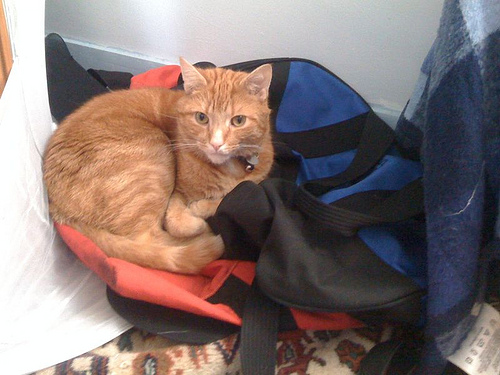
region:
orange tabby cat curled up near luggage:
[43, 57, 280, 266]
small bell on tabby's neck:
[235, 149, 267, 176]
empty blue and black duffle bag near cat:
[157, 47, 454, 330]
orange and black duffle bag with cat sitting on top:
[40, 58, 369, 342]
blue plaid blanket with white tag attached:
[385, 0, 497, 369]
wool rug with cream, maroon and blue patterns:
[34, 319, 437, 374]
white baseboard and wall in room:
[55, 0, 445, 132]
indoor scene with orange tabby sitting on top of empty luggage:
[34, 0, 499, 372]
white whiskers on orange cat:
[159, 138, 279, 161]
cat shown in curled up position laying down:
[41, 56, 288, 270]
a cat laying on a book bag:
[22, 14, 476, 374]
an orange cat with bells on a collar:
[38, 46, 313, 297]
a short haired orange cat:
[37, 47, 342, 311]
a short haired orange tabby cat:
[28, 54, 338, 326]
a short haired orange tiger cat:
[44, 49, 331, 284]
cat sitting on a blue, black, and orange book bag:
[56, 25, 443, 335]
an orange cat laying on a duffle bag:
[31, 48, 456, 335]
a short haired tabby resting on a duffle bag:
[38, 50, 425, 352]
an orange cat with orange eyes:
[28, 19, 405, 318]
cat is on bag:
[63, 50, 308, 269]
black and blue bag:
[194, 69, 446, 331]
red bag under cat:
[55, 217, 330, 346]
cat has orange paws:
[149, 192, 236, 265]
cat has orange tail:
[94, 213, 225, 322]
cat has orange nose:
[182, 135, 234, 147]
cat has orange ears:
[183, 60, 264, 107]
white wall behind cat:
[126, 3, 295, 55]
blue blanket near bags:
[382, 38, 486, 373]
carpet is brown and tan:
[115, 330, 248, 374]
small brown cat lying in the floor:
[39, 64, 278, 277]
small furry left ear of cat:
[179, 54, 206, 96]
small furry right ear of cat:
[235, 62, 272, 97]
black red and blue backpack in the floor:
[48, 43, 436, 338]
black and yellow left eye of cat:
[194, 108, 209, 125]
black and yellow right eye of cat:
[228, 115, 247, 126]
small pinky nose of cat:
[208, 137, 223, 150]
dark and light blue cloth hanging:
[395, 5, 499, 368]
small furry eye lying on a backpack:
[41, 56, 276, 258]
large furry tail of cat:
[44, 204, 227, 278]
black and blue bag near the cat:
[166, 55, 431, 314]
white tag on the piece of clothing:
[443, 297, 496, 374]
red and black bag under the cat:
[49, 62, 369, 332]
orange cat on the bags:
[40, 53, 277, 278]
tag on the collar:
[238, 148, 261, 173]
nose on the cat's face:
[208, 136, 223, 151]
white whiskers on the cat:
[162, 134, 278, 159]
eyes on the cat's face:
[191, 109, 248, 129]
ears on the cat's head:
[175, 53, 274, 102]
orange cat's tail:
[71, 220, 227, 274]